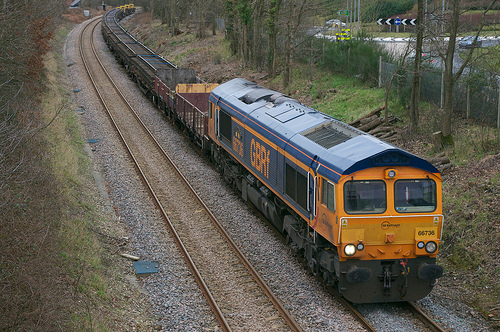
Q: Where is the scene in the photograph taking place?
A: In woods.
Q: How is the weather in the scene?
A: Cool and clear.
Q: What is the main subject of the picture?
A: A train.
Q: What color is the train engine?
A: Blue and yellow.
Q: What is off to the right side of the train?
A: A fence.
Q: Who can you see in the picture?
A: No one.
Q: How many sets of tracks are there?
A: 2.